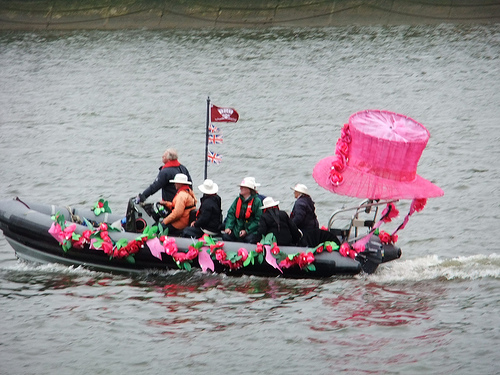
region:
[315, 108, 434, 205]
pink hat on a boat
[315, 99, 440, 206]
large pink hat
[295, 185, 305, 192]
white hat on a person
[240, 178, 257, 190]
white hat on a person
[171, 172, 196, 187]
white hat on a person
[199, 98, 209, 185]
black flag pole on boat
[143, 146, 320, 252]
people sitting on a boat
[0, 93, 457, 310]
black boat in the water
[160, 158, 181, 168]
red life jacket on man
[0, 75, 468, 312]
boat sailing in water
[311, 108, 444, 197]
large pink ladies hat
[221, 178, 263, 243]
person wearing red scarf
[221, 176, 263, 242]
person wearing green jacket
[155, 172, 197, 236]
person wearing orange jacket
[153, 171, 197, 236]
person in white hat steering boat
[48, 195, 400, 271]
pink flower garland with green leaves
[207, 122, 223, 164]
three small British flags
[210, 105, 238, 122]
red flag with white design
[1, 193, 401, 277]
small boat with motor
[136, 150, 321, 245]
people on a boat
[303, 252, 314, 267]
pink flower on boat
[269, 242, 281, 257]
pink flower on boat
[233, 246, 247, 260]
pink flower on boat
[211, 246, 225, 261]
pink flower on boat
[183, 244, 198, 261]
pink flower on boat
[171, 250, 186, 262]
pink flower on boat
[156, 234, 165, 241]
pink flower on boat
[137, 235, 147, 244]
pink flower on boat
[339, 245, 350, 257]
pink flower on boat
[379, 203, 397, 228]
pink flower on boat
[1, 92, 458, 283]
festive boat in water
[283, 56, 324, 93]
ripples in blue colored water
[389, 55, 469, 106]
ripples in blue colored water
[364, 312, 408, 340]
ripples in blue colored water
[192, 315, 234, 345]
ripples in blue colored water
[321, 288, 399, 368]
ripples in blue colored water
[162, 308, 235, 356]
ripples in blue colored water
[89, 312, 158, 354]
ripples in blue colored water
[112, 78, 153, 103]
ripples in blue colored water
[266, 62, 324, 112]
ripples in blue colored water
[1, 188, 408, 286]
black boat on the water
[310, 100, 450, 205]
pink hat on the boat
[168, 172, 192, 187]
white hat on the woman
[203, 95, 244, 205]
flags on the pole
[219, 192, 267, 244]
woman in a green coat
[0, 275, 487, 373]
water under the boat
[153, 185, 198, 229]
woman in an orange coat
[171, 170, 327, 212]
five white hats on the boat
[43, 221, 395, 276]
decorations on the side of the boat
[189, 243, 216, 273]
ribbon on the boat